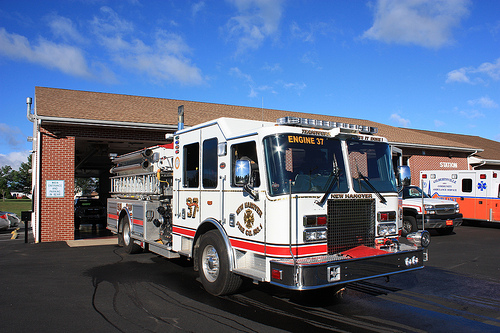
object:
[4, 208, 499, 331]
road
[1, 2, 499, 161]
sky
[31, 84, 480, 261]
building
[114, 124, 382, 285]
ambulance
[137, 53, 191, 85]
clouds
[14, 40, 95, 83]
clouds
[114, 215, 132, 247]
wheel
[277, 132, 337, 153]
engine 37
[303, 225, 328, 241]
lights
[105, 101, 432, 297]
ambulance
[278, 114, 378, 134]
sirens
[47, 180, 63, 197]
poster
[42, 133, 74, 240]
wall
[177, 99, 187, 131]
pipe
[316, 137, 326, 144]
number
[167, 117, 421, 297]
engine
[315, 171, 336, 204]
wipers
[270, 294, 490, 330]
streaks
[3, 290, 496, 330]
ground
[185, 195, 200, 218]
37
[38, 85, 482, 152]
roof